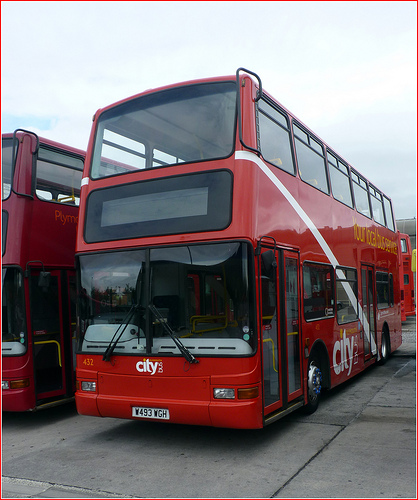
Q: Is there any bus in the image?
A: Yes, there is a bus.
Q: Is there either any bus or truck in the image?
A: Yes, there is a bus.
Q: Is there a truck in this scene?
A: No, there are no trucks.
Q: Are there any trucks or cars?
A: No, there are no trucks or cars.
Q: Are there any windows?
A: Yes, there is a window.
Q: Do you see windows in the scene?
A: Yes, there is a window.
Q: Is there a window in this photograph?
A: Yes, there is a window.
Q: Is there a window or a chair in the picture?
A: Yes, there is a window.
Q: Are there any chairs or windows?
A: Yes, there is a window.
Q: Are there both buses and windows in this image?
A: Yes, there are both a window and a bus.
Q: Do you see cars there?
A: No, there are no cars.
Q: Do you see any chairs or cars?
A: No, there are no cars or chairs.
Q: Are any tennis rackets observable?
A: No, there are no tennis rackets.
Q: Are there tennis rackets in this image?
A: No, there are no tennis rackets.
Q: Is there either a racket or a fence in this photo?
A: No, there are no rackets or fences.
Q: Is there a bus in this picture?
A: Yes, there is a bus.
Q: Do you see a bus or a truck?
A: Yes, there is a bus.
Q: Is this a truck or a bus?
A: This is a bus.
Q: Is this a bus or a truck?
A: This is a bus.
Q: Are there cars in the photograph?
A: No, there are no cars.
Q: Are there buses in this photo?
A: Yes, there is a bus.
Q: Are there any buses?
A: Yes, there is a bus.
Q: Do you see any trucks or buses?
A: Yes, there is a bus.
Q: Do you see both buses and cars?
A: No, there is a bus but no cars.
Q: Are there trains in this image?
A: No, there are no trains.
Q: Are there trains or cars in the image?
A: No, there are no trains or cars.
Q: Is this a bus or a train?
A: This is a bus.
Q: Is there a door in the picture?
A: Yes, there is a door.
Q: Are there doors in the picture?
A: Yes, there is a door.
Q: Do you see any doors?
A: Yes, there is a door.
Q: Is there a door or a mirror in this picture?
A: Yes, there is a door.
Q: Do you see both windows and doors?
A: Yes, there are both a door and a window.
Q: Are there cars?
A: No, there are no cars.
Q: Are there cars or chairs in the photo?
A: No, there are no cars or chairs.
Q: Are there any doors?
A: Yes, there are doors.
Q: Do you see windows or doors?
A: Yes, there are doors.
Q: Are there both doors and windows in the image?
A: Yes, there are both doors and a window.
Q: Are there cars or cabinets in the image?
A: No, there are no cars or cabinets.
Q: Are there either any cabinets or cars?
A: No, there are no cars or cabinets.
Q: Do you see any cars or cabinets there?
A: No, there are no cars or cabinets.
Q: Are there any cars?
A: No, there are no cars.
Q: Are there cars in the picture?
A: No, there are no cars.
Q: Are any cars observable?
A: No, there are no cars.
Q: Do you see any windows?
A: Yes, there is a window.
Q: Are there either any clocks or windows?
A: Yes, there is a window.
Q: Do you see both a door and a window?
A: Yes, there are both a window and a door.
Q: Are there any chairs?
A: No, there are no chairs.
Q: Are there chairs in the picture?
A: No, there are no chairs.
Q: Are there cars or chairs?
A: No, there are no chairs or cars.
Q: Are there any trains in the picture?
A: No, there are no trains.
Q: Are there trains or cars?
A: No, there are no trains or cars.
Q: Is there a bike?
A: No, there are no bikes.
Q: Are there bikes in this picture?
A: No, there are no bikes.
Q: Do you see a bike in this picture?
A: No, there are no bikes.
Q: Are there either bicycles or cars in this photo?
A: No, there are no bicycles or cars.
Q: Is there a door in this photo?
A: Yes, there are doors.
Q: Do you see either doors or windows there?
A: Yes, there are doors.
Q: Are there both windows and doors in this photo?
A: Yes, there are both doors and a window.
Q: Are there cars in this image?
A: No, there are no cars.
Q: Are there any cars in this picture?
A: No, there are no cars.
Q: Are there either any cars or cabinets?
A: No, there are no cars or cabinets.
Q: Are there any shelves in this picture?
A: No, there are no shelves.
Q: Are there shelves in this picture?
A: No, there are no shelves.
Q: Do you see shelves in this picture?
A: No, there are no shelves.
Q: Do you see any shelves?
A: No, there are no shelves.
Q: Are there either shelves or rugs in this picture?
A: No, there are no shelves or rugs.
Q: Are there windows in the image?
A: Yes, there is a window.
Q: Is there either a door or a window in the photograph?
A: Yes, there is a window.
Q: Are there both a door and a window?
A: Yes, there are both a window and a door.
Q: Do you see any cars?
A: No, there are no cars.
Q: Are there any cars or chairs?
A: No, there are no cars or chairs.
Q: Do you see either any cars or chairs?
A: No, there are no cars or chairs.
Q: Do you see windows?
A: Yes, there is a window.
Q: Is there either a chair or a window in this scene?
A: Yes, there is a window.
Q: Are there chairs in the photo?
A: No, there are no chairs.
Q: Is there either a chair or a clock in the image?
A: No, there are no chairs or clocks.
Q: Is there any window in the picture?
A: Yes, there is a window.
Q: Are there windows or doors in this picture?
A: Yes, there is a window.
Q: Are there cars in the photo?
A: No, there are no cars.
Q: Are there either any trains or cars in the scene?
A: No, there are no cars or trains.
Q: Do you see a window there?
A: Yes, there is a window.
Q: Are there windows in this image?
A: Yes, there is a window.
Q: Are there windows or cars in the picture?
A: Yes, there is a window.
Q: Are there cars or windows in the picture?
A: Yes, there is a window.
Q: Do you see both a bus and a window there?
A: Yes, there are both a window and a bus.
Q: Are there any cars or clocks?
A: No, there are no cars or clocks.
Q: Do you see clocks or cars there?
A: No, there are no cars or clocks.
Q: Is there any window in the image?
A: Yes, there is a window.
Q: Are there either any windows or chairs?
A: Yes, there is a window.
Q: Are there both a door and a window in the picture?
A: Yes, there are both a window and a door.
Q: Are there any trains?
A: No, there are no trains.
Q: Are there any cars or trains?
A: No, there are no trains or cars.